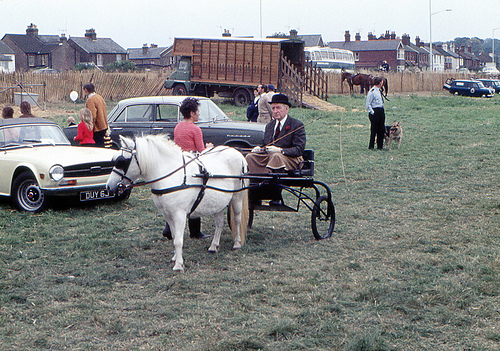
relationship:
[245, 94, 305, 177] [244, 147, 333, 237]
man riding on a cart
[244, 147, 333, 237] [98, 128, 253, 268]
cart being pulled by a white horse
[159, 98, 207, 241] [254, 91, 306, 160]
lady talking to a man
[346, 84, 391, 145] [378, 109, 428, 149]
man with a dog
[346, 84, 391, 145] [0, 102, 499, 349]
man standing in ground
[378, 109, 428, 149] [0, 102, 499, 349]
dog standing in ground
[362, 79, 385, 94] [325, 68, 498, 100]
horse standing by a fence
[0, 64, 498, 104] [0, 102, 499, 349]
fence at edge  of ground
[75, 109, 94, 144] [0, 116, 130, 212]
girl walking from car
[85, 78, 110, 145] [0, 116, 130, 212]
man walking from car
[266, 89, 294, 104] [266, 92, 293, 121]
hat on head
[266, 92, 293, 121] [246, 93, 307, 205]
head of man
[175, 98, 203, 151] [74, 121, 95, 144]
lady wears a shirt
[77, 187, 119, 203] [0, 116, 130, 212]
plate on a car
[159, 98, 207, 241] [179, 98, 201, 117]
lady has hair